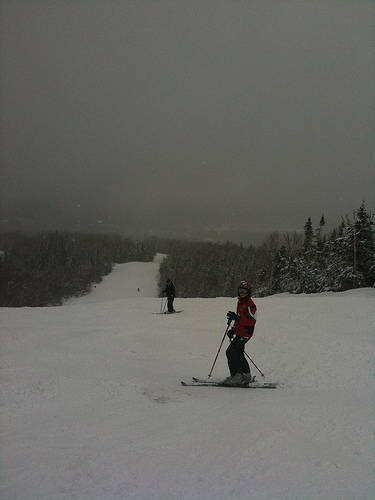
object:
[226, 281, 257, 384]
kid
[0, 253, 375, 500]
snow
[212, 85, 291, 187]
sky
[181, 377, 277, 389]
board